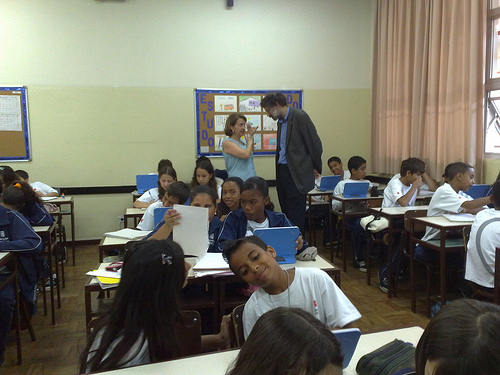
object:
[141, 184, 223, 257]
girl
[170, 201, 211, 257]
paper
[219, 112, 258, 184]
woman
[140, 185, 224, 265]
girl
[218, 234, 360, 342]
boy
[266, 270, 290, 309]
necklace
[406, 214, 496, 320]
desk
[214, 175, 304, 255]
girl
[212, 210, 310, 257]
jacket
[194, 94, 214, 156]
estudo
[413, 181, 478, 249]
white shirt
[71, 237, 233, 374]
student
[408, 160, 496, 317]
student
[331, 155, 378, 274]
student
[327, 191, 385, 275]
desk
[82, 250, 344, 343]
desk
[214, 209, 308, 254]
blue jacket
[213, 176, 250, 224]
girl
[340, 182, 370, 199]
laptop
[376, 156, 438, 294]
child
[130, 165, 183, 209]
child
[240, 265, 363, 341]
shirt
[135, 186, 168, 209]
shirt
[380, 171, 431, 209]
shirt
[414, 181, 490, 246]
shirt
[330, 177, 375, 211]
shirt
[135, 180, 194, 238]
student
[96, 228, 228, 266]
desk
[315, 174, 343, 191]
laptop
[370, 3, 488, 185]
curtain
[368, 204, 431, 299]
desk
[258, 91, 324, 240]
man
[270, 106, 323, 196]
gray jacket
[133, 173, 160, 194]
laptops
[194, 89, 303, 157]
board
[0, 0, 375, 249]
wall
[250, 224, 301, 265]
laptop computer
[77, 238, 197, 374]
children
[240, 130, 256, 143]
hand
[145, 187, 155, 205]
pencil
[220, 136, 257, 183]
blouse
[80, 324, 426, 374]
desk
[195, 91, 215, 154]
brown surface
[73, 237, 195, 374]
dark hair